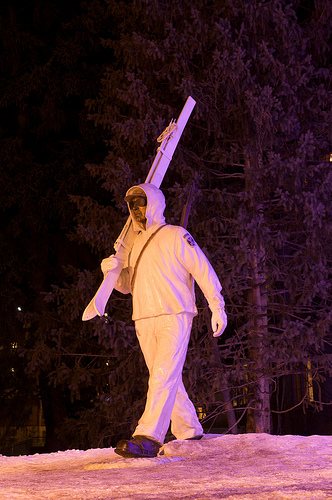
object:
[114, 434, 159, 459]
boots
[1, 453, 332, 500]
snow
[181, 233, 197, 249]
patch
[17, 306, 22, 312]
lights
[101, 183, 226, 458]
man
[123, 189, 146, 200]
baseball cap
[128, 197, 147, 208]
sunglasses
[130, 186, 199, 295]
rifle strap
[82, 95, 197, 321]
skis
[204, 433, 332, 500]
slushy snow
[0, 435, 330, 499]
trail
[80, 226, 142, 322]
mans shoulder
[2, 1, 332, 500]
picture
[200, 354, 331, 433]
house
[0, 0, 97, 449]
trees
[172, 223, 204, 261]
shoulder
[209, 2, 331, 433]
trees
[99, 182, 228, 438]
outfit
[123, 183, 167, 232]
hood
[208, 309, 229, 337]
gloves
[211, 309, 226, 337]
hand